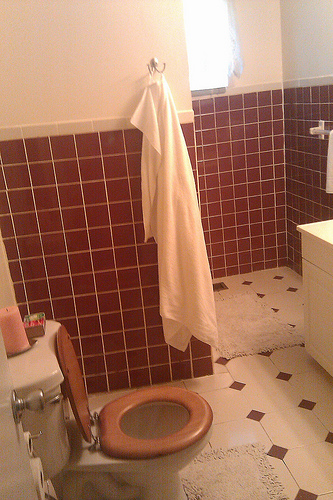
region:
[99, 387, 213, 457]
toilet seat made of wood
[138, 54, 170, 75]
hook for holding robes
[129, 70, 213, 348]
white towel hanging on rack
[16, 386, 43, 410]
silver doorknob on door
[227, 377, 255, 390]
diamond shape design on tile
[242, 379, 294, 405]
square white tile floor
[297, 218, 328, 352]
bathroom white sink's counter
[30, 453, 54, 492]
toilet tissue on roll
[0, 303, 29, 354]
pink candle on toilet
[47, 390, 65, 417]
toilet handle for flushing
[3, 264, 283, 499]
a nice bathroom area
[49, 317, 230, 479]
a brown toilet seat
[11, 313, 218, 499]
a white toilet for using the bathroom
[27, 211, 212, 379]
brown tile wall in the bathroom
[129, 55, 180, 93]
a hook for towels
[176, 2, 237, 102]
a window in the bathroom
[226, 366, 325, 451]
brown and white tiles on the floor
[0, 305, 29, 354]
a pink candle on the toilet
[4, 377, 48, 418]
a door knob on the door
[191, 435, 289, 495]
a white bathroom rug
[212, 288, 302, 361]
white shag bathroom mat for shower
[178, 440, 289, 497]
white shag bathroom mat for toilet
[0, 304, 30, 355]
pink pillar candle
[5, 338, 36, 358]
flat silver candle holder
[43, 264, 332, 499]
white tile floor with brown diamond tile accents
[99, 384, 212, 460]
wooden toilet seat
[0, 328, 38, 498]
white wooden bathroom door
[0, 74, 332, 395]
brown and white tiled lower wall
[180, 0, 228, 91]
small bathroom window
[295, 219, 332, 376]
white bathroom cabinet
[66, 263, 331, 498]
White tiles with a brown diamond pattern.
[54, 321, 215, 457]
A brown wooden toilet seat.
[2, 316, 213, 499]
A white toilet.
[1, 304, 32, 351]
A pink candle.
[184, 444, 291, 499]
A white toilet rug.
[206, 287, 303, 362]
A white bathroom rug.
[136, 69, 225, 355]
White towels hanging up.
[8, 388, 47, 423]
A silver doorknob.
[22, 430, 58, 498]
White rolls of toilet paper.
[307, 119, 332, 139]
A towel rack.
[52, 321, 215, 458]
wooden toilet seat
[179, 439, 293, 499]
white bathroom rug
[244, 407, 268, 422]
brown diamond-shaped floor tile accent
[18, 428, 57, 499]
white toilet paper rolls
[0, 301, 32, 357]
candle on toilet tank lid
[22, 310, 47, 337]
box of matches on toilet tank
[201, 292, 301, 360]
white rectangular floor rug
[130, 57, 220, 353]
white bathroom towel hanging on wall hook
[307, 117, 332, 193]
white towel on chrome and white ceramic towel holder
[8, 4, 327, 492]
sunny bathroom with tile floor and partially-tiled walls